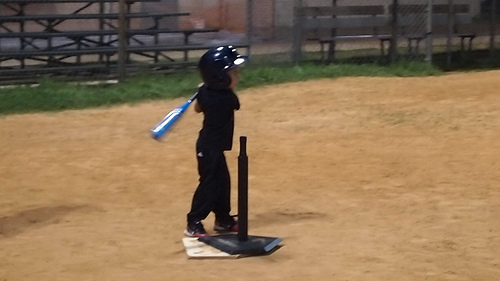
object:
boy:
[185, 42, 247, 235]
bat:
[149, 91, 196, 140]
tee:
[235, 137, 247, 244]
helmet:
[196, 43, 249, 84]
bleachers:
[0, 0, 254, 83]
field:
[0, 32, 499, 281]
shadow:
[0, 195, 94, 237]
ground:
[0, 63, 499, 281]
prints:
[410, 241, 456, 254]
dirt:
[0, 70, 499, 281]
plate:
[181, 232, 284, 262]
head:
[195, 46, 246, 89]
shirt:
[191, 83, 239, 150]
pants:
[186, 152, 233, 224]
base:
[179, 236, 240, 259]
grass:
[0, 46, 499, 118]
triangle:
[197, 234, 282, 254]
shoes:
[181, 220, 208, 237]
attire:
[194, 84, 240, 151]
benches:
[300, 5, 395, 63]